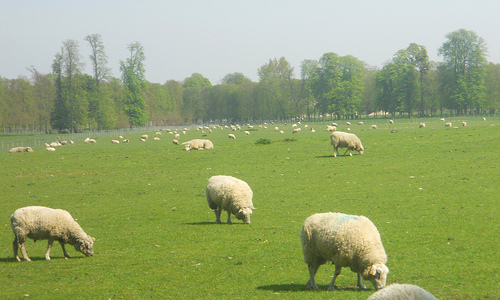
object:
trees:
[0, 28, 500, 135]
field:
[0, 115, 497, 300]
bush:
[254, 138, 272, 145]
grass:
[0, 115, 500, 300]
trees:
[433, 29, 493, 117]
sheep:
[331, 131, 365, 157]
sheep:
[183, 139, 214, 151]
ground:
[356, 65, 397, 120]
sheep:
[112, 140, 119, 144]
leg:
[59, 240, 70, 257]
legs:
[12, 229, 31, 259]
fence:
[0, 124, 198, 150]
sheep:
[370, 125, 378, 130]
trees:
[304, 52, 367, 119]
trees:
[375, 43, 427, 118]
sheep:
[9, 205, 95, 261]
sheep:
[300, 211, 389, 291]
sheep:
[206, 175, 257, 225]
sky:
[0, 0, 500, 86]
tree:
[49, 33, 147, 133]